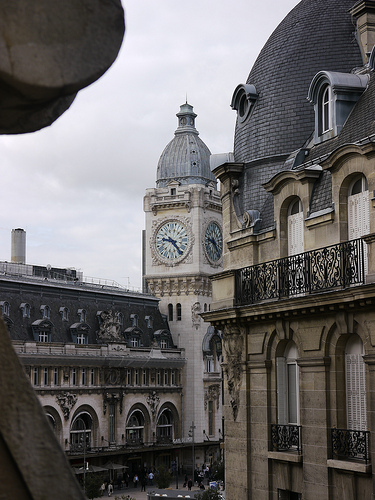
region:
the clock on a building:
[121, 209, 211, 280]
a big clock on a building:
[137, 186, 231, 283]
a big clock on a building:
[142, 211, 215, 265]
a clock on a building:
[136, 198, 259, 275]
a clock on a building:
[147, 213, 215, 277]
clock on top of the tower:
[154, 211, 200, 279]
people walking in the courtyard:
[103, 466, 223, 494]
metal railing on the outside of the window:
[269, 421, 305, 451]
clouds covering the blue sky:
[45, 156, 121, 241]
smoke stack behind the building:
[10, 218, 29, 260]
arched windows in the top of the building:
[276, 193, 304, 291]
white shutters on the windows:
[281, 217, 306, 289]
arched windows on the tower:
[164, 300, 188, 323]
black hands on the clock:
[158, 232, 185, 259]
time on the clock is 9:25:
[147, 207, 192, 269]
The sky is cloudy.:
[136, 11, 231, 72]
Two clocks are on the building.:
[154, 220, 221, 266]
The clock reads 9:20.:
[159, 236, 184, 254]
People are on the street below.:
[118, 470, 155, 492]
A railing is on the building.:
[267, 423, 301, 452]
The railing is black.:
[268, 422, 300, 450]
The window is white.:
[278, 361, 297, 421]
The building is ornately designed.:
[54, 305, 156, 431]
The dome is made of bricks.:
[289, 13, 330, 64]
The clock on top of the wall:
[145, 216, 199, 270]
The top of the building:
[154, 89, 218, 188]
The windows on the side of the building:
[256, 324, 371, 462]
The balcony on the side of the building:
[259, 390, 373, 473]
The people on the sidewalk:
[91, 459, 217, 496]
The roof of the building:
[236, 4, 355, 220]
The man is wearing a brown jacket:
[128, 467, 142, 491]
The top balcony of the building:
[214, 227, 374, 318]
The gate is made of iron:
[235, 239, 363, 301]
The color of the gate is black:
[235, 237, 361, 314]